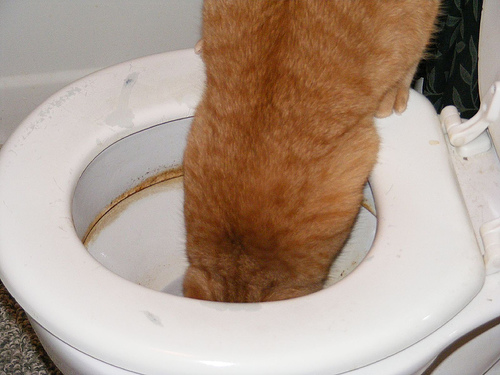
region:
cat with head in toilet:
[1, 1, 496, 371]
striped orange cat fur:
[185, 2, 435, 299]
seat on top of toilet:
[1, 40, 483, 372]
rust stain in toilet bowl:
[81, 120, 376, 280]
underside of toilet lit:
[446, 0, 498, 267]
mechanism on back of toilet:
[440, 85, 498, 269]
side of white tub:
[0, 0, 202, 142]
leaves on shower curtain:
[418, 0, 483, 113]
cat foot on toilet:
[376, 62, 417, 119]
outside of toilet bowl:
[24, 312, 125, 373]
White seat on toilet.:
[153, 311, 228, 346]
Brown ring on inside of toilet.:
[98, 173, 163, 204]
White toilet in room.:
[436, 337, 458, 357]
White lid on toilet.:
[478, 79, 495, 106]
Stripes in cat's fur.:
[208, 217, 269, 270]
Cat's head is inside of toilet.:
[194, 264, 251, 295]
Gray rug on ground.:
[10, 350, 29, 365]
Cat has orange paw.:
[379, 84, 409, 91]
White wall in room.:
[18, 18, 73, 63]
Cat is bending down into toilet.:
[148, 62, 357, 263]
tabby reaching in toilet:
[182, 1, 417, 288]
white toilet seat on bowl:
[5, 59, 480, 342]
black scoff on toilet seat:
[148, 296, 165, 336]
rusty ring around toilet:
[111, 170, 173, 215]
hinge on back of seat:
[425, 93, 478, 153]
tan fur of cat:
[216, 141, 301, 225]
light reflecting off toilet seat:
[178, 337, 241, 373]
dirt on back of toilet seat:
[433, 127, 496, 230]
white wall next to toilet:
[7, 2, 222, 95]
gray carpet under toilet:
[2, 296, 47, 373]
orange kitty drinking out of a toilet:
[164, 5, 464, 317]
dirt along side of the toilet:
[99, 187, 134, 237]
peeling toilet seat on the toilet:
[108, 74, 159, 134]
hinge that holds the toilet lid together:
[432, 91, 474, 154]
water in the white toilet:
[157, 267, 189, 294]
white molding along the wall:
[8, 55, 64, 100]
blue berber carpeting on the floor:
[2, 318, 28, 368]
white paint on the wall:
[22, 12, 109, 46]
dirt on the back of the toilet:
[438, 127, 498, 244]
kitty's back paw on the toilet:
[381, 72, 418, 124]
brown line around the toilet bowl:
[81, 156, 208, 243]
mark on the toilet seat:
[141, 308, 166, 329]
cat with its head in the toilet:
[167, 1, 379, 316]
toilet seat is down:
[2, 43, 495, 363]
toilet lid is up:
[427, 4, 498, 264]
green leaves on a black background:
[410, 4, 492, 116]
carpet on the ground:
[1, 292, 61, 374]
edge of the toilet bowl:
[22, 326, 83, 373]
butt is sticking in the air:
[191, 0, 437, 109]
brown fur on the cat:
[181, 0, 431, 310]